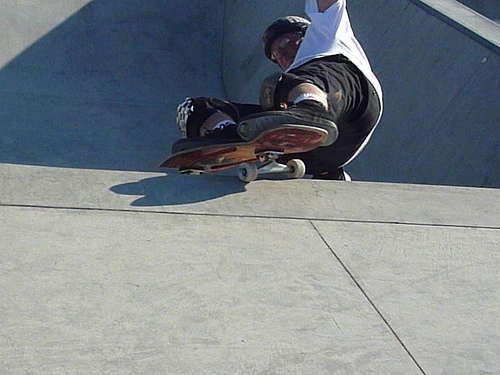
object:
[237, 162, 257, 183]
wheel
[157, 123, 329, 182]
board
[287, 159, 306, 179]
wheel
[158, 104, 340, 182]
skate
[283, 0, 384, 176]
shirt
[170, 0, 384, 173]
boy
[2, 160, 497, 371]
ramp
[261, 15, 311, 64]
helmet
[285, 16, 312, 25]
lettering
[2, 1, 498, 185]
wall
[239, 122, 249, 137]
hole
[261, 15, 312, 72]
head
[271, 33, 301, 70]
face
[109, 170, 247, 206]
shadow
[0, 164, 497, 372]
ground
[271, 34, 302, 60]
eyeglasses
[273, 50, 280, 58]
eye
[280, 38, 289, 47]
eye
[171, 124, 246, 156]
shoe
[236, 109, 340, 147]
shoe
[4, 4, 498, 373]
skate park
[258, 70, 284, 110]
knee pads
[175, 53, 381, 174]
pants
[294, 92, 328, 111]
socks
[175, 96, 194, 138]
kneepad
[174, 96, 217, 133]
knee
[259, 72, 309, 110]
knee